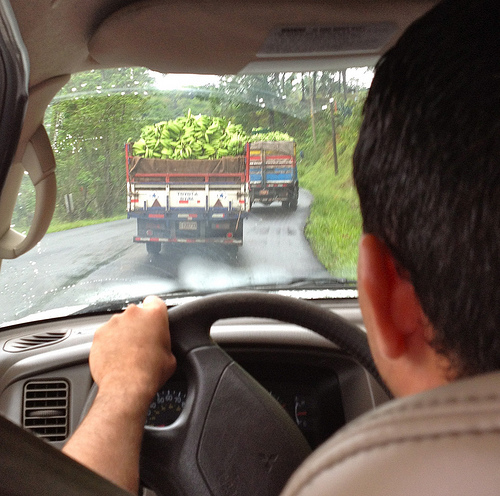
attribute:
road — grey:
[221, 234, 305, 286]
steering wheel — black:
[83, 288, 392, 494]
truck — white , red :
[122, 137, 252, 264]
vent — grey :
[21, 374, 72, 443]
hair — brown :
[352, 7, 499, 381]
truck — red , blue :
[243, 135, 298, 210]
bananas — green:
[123, 113, 253, 158]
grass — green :
[294, 156, 365, 266]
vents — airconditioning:
[21, 383, 66, 435]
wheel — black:
[145, 227, 160, 259]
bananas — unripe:
[144, 115, 254, 152]